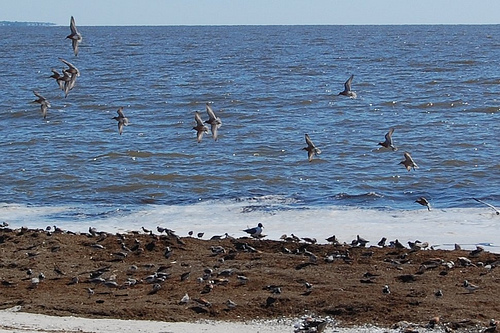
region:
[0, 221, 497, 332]
beach covered by birds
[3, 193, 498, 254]
foam on the surface of the water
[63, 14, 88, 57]
the highest bird in the air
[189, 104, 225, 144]
two birds flying close to each other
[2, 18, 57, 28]
a promontory in the distance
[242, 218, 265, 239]
a large bird in the midst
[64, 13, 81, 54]
a bird with wings wide open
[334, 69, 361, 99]
bird with wings overhead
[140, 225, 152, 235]
small white bird on the beach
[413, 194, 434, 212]
a bird about to land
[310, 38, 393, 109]
dark blue water and black birds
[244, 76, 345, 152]
dark blue water and black birds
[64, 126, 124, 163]
dark blue water and black birds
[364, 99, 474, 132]
dark blue water and black birds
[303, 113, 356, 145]
dark blue water and black birds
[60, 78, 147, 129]
dark blue water and black birds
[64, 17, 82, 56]
a bird is in flight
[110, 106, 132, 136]
a bird is in flight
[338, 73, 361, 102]
a bird is in flight over water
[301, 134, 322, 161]
a bird is in flight over water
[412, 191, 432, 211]
a bird is in flight over water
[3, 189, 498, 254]
white foam on top of water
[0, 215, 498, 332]
birds are covering a sandy area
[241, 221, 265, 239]
a bird is standing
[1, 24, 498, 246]
large swath of water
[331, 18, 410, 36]
white clouds in blue sky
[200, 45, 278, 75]
ripples in dark blue water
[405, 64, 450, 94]
ripples in dark blue water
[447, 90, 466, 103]
ripples in dark blue water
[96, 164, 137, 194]
ripples in dark blue water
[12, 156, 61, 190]
ripples in dark blue water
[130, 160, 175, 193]
ripples in dark blue water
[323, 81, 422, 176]
birds flying in the sky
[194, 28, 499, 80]
small waves of ocean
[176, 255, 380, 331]
brown sand on the beach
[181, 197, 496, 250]
sea foam in the ocean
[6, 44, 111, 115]
group of birds flying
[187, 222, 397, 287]
birds walking on the beach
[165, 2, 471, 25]
clear blue sky no clouds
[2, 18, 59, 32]
a pier in the background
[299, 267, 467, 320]
brown sand with birds walking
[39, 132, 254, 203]
ocean water with birds above